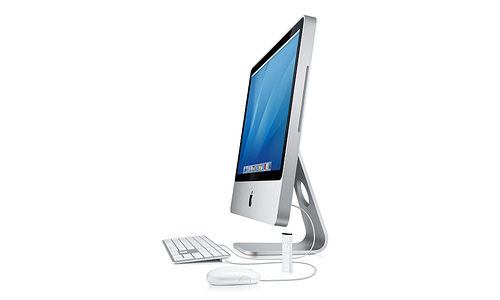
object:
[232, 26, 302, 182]
screen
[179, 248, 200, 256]
pad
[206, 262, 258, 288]
mouse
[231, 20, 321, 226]
computer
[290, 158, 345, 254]
stand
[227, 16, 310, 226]
monitor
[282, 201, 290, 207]
usb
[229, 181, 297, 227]
bottom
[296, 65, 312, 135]
disk drive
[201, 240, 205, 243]
keys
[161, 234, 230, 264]
keyboard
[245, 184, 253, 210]
logo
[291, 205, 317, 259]
cord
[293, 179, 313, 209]
hole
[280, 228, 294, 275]
drive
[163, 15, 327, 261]
imac